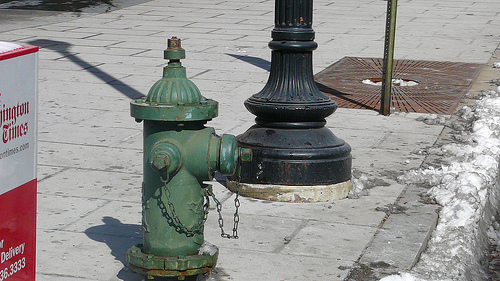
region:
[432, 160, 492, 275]
snow on the curb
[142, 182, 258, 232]
chain on the fire hydrant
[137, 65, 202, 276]
green fire hydrant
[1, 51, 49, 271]
paper machine on the sidewalk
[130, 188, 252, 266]
fire hydrant on the sidewalk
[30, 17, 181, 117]
shadow of the pole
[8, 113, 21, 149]
Times written in red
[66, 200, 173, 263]
fire hydrant shadow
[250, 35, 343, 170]
pole is black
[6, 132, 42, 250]
newspaper machine is red and white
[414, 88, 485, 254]
Snow on the sidewalk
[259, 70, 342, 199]
rust at the bottom of the pole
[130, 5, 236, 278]
green fire hydrant on the sidewalk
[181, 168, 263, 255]
chain hanging of the hydrant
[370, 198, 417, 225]
sidewalk is wet on the side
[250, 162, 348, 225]
The cement is chipping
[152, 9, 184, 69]
Nozzle on top of the hydrant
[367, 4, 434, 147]
Green metal pole on sidewalk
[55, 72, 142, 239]
Stains on the concrete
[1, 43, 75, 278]
Sign sitting on the pavement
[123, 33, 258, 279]
green fire hydrant on sidewalk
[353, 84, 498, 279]
dirty snow along curb and on sidewalk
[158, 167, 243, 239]
chains on fire hydrant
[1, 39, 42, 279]
coin operated newspaper rack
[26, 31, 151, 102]
shadow from streetlight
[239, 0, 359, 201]
street light on sidewalk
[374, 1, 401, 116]
sign for pole in concrete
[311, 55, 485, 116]
manhole cover in sidewalk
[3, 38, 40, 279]
Washinton times newspaper box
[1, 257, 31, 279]
partial phone number on newspaper box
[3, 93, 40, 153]
washington times words on white and red background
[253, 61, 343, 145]
black decorative base of metal pole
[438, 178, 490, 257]
dirty white snow on side of curve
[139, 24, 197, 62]
top metal bolt on top of fire hydrant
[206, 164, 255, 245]
silver chain on right of hydrant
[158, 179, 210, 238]
silver chain on left of hydrant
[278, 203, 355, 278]
cement pavement on ground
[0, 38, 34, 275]
red and white newspaper box on street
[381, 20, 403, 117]
green street sign pole on sidewalk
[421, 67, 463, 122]
brown slated grate on sidewalk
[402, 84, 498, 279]
Snow on the curb.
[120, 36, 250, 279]
A green fire hydrant.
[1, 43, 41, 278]
Red and white newspaper box.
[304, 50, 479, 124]
A drain in a square design on the sidewalk.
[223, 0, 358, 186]
Bottom of a black pole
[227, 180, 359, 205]
Round concrete that the black pole is sitting on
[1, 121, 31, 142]
The word Times written in red.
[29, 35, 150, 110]
The fire hydrant shadow.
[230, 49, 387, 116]
The sign pole shadow.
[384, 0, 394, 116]
A green pole with a sign ontop.